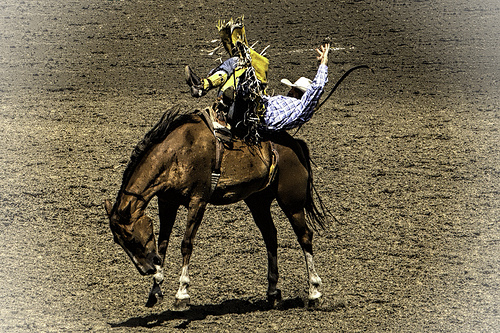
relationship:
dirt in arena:
[3, 1, 498, 324] [344, 27, 480, 298]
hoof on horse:
[247, 271, 297, 326] [102, 104, 349, 311]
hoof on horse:
[292, 268, 328, 329] [102, 104, 349, 311]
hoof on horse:
[164, 284, 199, 316] [102, 104, 349, 311]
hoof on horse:
[137, 275, 162, 314] [102, 104, 349, 311]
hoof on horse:
[143, 285, 165, 310] [71, 111, 360, 331]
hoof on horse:
[167, 288, 192, 314] [71, 111, 360, 331]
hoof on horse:
[302, 289, 326, 309] [71, 111, 360, 331]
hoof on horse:
[264, 285, 282, 311] [71, 111, 360, 331]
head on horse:
[97, 194, 168, 282] [67, 106, 339, 316]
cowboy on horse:
[180, 42, 342, 136] [102, 104, 349, 311]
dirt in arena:
[0, 0, 498, 332] [2, 4, 497, 330]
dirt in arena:
[3, 1, 498, 324] [2, 4, 497, 330]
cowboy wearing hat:
[180, 21, 331, 136] [282, 73, 319, 96]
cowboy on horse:
[180, 21, 331, 136] [102, 104, 349, 311]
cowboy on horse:
[180, 42, 342, 136] [100, 87, 346, 314]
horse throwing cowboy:
[102, 104, 349, 311] [180, 42, 342, 136]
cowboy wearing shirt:
[180, 42, 342, 136] [265, 62, 329, 127]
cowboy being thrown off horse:
[180, 42, 342, 136] [92, 101, 332, 326]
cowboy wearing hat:
[180, 42, 342, 136] [277, 77, 312, 89]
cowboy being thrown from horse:
[180, 42, 342, 136] [102, 104, 349, 311]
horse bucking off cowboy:
[99, 104, 348, 313] [180, 42, 342, 136]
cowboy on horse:
[180, 42, 342, 136] [86, 32, 398, 286]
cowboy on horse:
[180, 42, 342, 136] [84, 101, 354, 319]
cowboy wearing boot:
[180, 42, 342, 136] [180, 65, 228, 99]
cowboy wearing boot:
[180, 42, 342, 136] [213, 84, 235, 115]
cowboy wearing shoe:
[180, 42, 342, 136] [182, 70, 229, 92]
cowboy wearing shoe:
[180, 42, 342, 136] [208, 69, 255, 120]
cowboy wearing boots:
[180, 42, 342, 136] [190, 59, 227, 120]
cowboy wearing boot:
[180, 42, 342, 136] [175, 58, 229, 99]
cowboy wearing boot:
[180, 42, 342, 136] [215, 72, 248, 122]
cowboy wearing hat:
[180, 42, 342, 136] [283, 69, 318, 90]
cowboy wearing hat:
[180, 42, 342, 136] [281, 76, 314, 92]